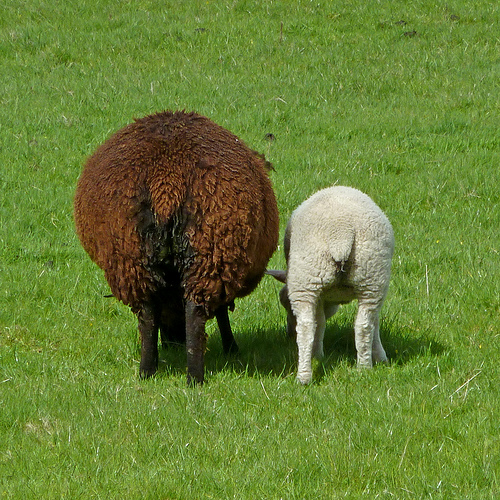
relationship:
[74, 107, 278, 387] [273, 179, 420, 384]
animal next to sheep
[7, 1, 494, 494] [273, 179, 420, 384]
grass under sheep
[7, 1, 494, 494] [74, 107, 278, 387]
grass under animal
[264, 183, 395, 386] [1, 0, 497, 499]
animal grazing on field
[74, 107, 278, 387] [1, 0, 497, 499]
animal grazing on field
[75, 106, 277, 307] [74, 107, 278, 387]
butt on animal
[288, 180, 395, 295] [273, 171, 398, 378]
butt on sheep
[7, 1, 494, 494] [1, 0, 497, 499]
grass covering field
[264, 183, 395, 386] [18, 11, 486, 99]
animal in a field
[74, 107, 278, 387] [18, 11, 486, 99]
animal in a field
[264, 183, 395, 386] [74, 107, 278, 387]
animal standing next to a animal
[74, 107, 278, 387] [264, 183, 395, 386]
animal standing next to a animal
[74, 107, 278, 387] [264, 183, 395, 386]
animal eating next to animal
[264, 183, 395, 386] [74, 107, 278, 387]
animal eating next to animal